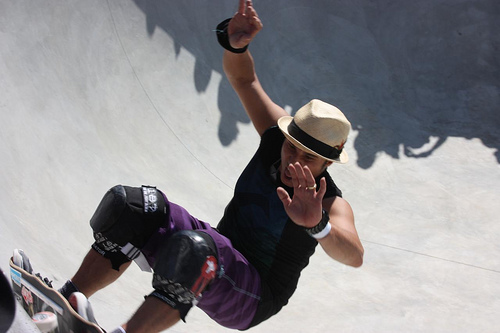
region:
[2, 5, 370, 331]
a man on a skateboard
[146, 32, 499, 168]
shadows of the spectators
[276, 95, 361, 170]
a hat with a black stripe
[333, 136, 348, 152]
feather in the hat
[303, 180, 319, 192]
ring on the man's left hand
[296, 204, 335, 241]
two bracelets on the left wrist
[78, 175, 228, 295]
a pair of black knee pads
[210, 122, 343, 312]
black colored tank top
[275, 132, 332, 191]
man's shaded face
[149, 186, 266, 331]
pair of purple colored shorts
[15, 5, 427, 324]
a man on a skateboard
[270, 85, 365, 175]
man is wearing a hat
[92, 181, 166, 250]
black knee pad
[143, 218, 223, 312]
a knee pad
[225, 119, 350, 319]
man is wearing a black sleeveless shirt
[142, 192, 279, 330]
man has a pair of purple shorts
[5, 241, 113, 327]
a skateboard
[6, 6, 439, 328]
a man rides a skateboard around a half pipe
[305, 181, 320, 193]
man has on a gold ring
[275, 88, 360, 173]
skater with a porkpie hat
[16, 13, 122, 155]
gray wall of skate park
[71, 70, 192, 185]
gray wall of skate park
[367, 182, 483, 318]
gray wall of skate park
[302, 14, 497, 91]
gray wall in shadow at skate park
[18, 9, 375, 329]
young man riding skateboard at skating park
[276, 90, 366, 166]
tan and black hat on young man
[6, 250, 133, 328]
skateboard ridden by young man at skate park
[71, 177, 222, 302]
black knee pads worn by young man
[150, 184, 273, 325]
purple pants worn by young man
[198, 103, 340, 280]
black shirt worn by young man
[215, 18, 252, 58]
The black wrist band on the skater's left wrist.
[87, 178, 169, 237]
The skater's left knee pad.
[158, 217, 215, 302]
The skater's right knee pad.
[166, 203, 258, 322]
The purple shorts worn by the skater.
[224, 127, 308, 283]
The black tank top worn by the skater.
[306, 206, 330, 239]
The black watch on the skater's right wrist.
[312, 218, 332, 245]
The white wrist band on the skater's right wrist.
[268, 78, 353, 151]
The tan hat worn by the skater.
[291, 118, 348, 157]
The black ribbon around the tan hat.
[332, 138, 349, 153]
The red feather in the tan hat.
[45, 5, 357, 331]
man in hat skateboarding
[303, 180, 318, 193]
wedding ring on finger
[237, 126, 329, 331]
black sleeveless tee shirt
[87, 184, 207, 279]
black pads on knees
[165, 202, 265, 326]
purple shorts on man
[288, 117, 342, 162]
black band around hat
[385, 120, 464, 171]
shadow on skate ramp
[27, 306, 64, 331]
wheel on bottom of skateboard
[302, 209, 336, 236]
black watch on wrist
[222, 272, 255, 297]
stripe on man's shorts